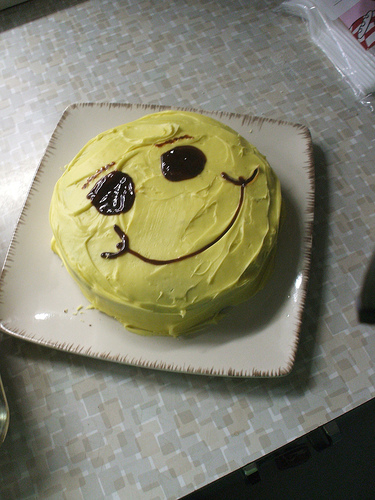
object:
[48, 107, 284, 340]
frosting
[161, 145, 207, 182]
black icing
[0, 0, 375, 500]
table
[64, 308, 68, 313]
crumbs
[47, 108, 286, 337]
cake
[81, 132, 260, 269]
smiley face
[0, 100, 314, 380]
plate